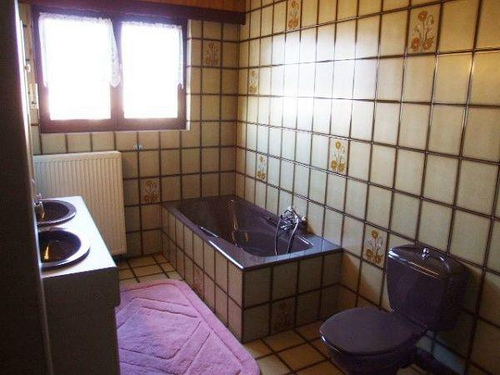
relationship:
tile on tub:
[146, 192, 347, 356] [159, 181, 345, 368]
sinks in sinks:
[35, 187, 128, 374] [35, 194, 120, 375]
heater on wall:
[29, 147, 138, 267] [14, 11, 247, 287]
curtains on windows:
[24, 19, 197, 96] [27, 11, 199, 145]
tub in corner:
[159, 181, 345, 368] [188, 6, 271, 313]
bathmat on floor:
[78, 283, 269, 374] [51, 258, 400, 373]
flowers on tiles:
[324, 160, 348, 173] [320, 132, 358, 181]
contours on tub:
[196, 214, 304, 269] [159, 181, 345, 368]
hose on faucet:
[261, 216, 313, 262] [279, 203, 310, 238]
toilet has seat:
[311, 238, 488, 374] [316, 297, 421, 374]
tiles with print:
[320, 132, 358, 181] [311, 124, 368, 189]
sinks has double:
[35, 194, 120, 375] [31, 194, 90, 276]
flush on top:
[416, 242, 438, 265] [382, 237, 474, 332]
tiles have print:
[320, 132, 358, 181] [311, 124, 368, 189]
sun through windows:
[42, 81, 186, 126] [27, 11, 199, 145]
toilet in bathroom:
[311, 238, 488, 374] [14, 46, 498, 339]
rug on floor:
[78, 283, 269, 374] [51, 258, 400, 373]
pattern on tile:
[416, 17, 434, 47] [402, 4, 440, 61]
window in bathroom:
[27, 11, 199, 145] [14, 46, 498, 339]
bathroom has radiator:
[14, 46, 498, 339] [29, 147, 138, 267]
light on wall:
[262, 36, 374, 136] [242, 5, 496, 349]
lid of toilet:
[309, 306, 448, 360] [311, 238, 488, 374]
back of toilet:
[380, 259, 467, 330] [311, 238, 488, 374]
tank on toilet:
[380, 238, 468, 349] [311, 238, 488, 374]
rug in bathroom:
[78, 283, 269, 374] [14, 46, 498, 339]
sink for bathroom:
[28, 226, 92, 271] [14, 46, 498, 339]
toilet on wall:
[311, 238, 488, 374] [242, 5, 496, 349]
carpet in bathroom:
[78, 283, 269, 374] [14, 46, 498, 339]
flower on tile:
[404, 33, 424, 56] [402, 4, 440, 61]